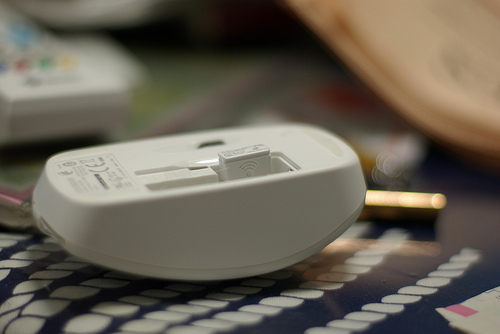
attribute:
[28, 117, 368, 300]
mouse — upside down, white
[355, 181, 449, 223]
object — blurry, shiny, gold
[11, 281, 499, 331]
cloth — blue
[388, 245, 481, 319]
design — rope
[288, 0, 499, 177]
object — blurry, tan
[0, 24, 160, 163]
object — blurry, white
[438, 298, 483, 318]
rectangle — small, pink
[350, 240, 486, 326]
design — white, rope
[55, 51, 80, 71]
button — yellow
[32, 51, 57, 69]
button — green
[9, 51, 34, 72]
button — red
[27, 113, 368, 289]
charger — white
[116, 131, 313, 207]
charger — white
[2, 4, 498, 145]
background — blurred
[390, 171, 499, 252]
table — blue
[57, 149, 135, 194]
sticker — white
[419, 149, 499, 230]
desk — blue, white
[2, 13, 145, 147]
phone — blurry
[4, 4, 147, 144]
phone — white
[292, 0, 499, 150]
object — brown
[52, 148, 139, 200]
text —  gray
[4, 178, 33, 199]
object —  pink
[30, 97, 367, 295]
mouse — white, computer 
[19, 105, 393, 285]
mouse — Computer , upside down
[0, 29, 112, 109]
icon — wifi bars 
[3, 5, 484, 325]
photo — indoors